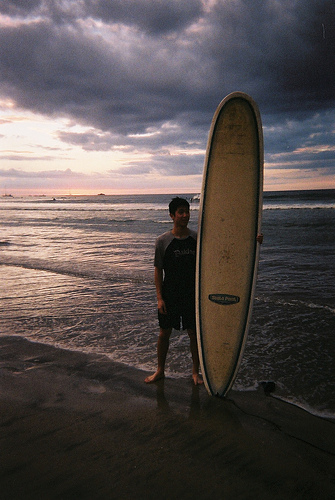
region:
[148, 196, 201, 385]
this is a man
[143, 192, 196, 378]
the boy is standing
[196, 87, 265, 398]
this is a surfboard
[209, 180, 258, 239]
the board is white in color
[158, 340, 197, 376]
the legs are short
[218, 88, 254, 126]
the top isnsharp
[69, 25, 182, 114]
these are the clouds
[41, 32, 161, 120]
the clouds are dark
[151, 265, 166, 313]
this is the hand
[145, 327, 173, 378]
this is a leg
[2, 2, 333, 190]
dark clouds in sky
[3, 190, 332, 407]
surface of ocean water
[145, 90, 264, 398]
man standing with surfboard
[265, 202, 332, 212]
white water of crashed wave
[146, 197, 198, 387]
young man in tee shirt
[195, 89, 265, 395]
hand holding surfboard vertically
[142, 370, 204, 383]
bare feet on sand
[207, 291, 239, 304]
logo on surf board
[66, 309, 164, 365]
sea foam on moving water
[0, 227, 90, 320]
light reflection on water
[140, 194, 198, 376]
this is a boy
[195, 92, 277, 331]
this is a surf board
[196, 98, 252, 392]
the surf board is white in color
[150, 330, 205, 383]
the boy is light skinned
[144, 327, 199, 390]
the boy is bare footed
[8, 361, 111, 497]
this is the beach sand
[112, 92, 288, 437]
man with surf board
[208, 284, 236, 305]
graphic on the board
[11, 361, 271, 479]
sand on the ground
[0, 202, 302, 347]
water at the beach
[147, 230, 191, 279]
shirt on the man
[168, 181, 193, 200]
people in the water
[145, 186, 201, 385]
man standing on sand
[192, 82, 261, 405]
board in man's hand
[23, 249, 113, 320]
ripples near the shore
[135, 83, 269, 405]
A young man holding up a surfboard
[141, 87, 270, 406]
A young man holding up a surfboard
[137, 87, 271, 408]
A young man holding up a surfboard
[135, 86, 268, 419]
A young man holding up a surfboard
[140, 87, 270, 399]
A young man holding up a surfboard